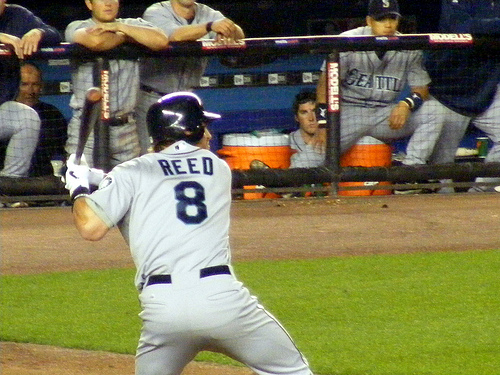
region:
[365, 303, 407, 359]
the grass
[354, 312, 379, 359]
the grass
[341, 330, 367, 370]
the grass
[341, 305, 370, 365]
the grass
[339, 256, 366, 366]
the grass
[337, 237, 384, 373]
the grass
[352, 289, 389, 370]
the grass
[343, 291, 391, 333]
part of a green ground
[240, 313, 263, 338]
part of a trouser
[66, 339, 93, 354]
edge of a field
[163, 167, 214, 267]
part of a number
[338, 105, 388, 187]
part of a fence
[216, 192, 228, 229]
edge of a top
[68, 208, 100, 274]
part of an elbow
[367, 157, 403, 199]
edge of a metal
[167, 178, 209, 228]
jersey number print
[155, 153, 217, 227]
name and number print on the back of a jersey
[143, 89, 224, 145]
baseball player helmet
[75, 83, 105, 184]
bat in the player's hand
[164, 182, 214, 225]
the number 8 on the back of a baseball jersey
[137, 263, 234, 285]
belt around the baseball player's waist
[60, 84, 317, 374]
baseball player preparing to swing his bat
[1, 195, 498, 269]
strip of dirt on the field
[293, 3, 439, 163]
baseball player in the stands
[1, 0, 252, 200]
baseball players hanging on the rail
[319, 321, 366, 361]
the grass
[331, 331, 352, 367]
the grass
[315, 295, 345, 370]
the grass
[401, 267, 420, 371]
the grass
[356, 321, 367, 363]
the grass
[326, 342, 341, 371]
the grass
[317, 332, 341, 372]
the grass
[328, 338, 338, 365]
the grass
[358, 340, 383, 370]
the grass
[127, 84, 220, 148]
player has black helmet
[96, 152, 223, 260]
player has grey shirt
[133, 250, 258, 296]
player has black belt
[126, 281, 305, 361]
player has grey pants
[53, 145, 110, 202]
player has white gloves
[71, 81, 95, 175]
player has brown bat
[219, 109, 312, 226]
orange and white drink dispenser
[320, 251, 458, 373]
infield grass is green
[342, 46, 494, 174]
mesh fencing over dugout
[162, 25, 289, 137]
blue wall in dugout